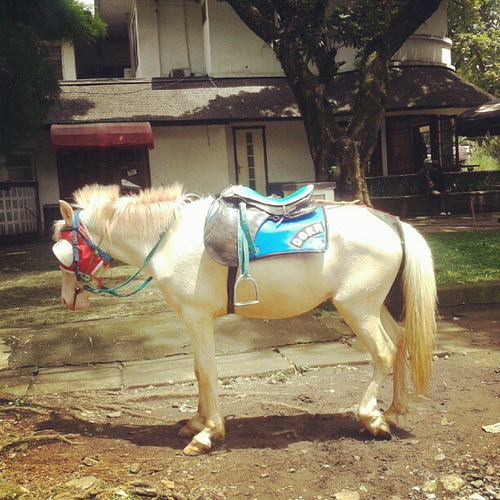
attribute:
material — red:
[53, 221, 103, 276]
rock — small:
[128, 457, 142, 472]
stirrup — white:
[232, 272, 259, 307]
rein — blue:
[72, 211, 179, 291]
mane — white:
[75, 182, 197, 235]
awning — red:
[47, 124, 150, 144]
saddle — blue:
[202, 175, 332, 266]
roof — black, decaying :
[55, 58, 497, 143]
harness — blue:
[68, 195, 188, 301]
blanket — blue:
[208, 193, 324, 257]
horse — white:
[54, 164, 431, 473]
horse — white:
[50, 182, 437, 457]